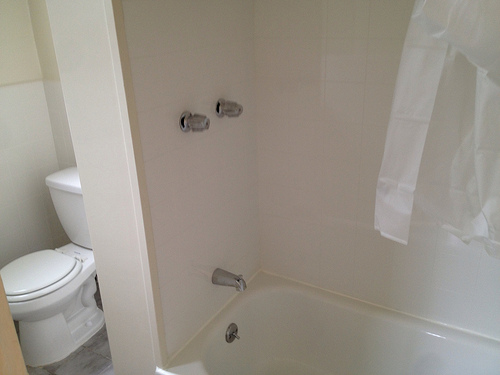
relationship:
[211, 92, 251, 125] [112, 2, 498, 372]
knob on shower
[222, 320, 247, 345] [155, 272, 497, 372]
stopper in tub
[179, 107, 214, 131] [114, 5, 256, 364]
knob on wall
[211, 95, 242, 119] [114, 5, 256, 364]
knob on wall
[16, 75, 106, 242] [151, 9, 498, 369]
tile on wall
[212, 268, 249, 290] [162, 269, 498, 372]
faucet of bath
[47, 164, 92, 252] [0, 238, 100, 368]
tank of toilet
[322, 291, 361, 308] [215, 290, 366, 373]
rim of tub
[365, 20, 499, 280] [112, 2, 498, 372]
curtain of shower